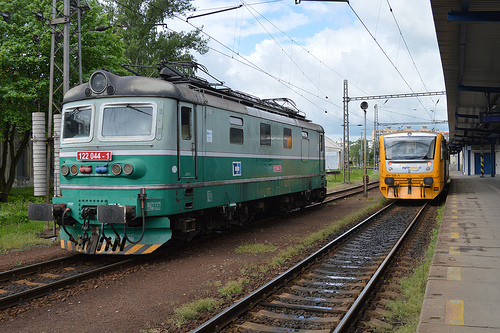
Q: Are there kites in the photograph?
A: No, there are no kites.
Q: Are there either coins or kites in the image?
A: No, there are no kites or coins.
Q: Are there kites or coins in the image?
A: No, there are no kites or coins.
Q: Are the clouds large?
A: Yes, the clouds are large.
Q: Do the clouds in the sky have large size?
A: Yes, the clouds are large.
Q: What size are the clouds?
A: The clouds are large.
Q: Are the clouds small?
A: No, the clouds are large.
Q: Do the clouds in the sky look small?
A: No, the clouds are large.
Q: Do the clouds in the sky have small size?
A: No, the clouds are large.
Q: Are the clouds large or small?
A: The clouds are large.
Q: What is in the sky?
A: The clouds are in the sky.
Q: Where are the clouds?
A: The clouds are in the sky.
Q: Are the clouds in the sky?
A: Yes, the clouds are in the sky.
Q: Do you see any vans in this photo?
A: No, there are no vans.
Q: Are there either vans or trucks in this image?
A: No, there are no vans or trucks.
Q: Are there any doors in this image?
A: Yes, there is a door.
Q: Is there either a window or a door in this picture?
A: Yes, there is a door.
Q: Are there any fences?
A: No, there are no fences.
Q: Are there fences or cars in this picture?
A: No, there are no fences or cars.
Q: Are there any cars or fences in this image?
A: No, there are no fences or cars.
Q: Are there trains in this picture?
A: Yes, there is a train.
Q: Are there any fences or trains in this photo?
A: Yes, there is a train.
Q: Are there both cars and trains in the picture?
A: No, there is a train but no cars.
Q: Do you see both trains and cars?
A: No, there is a train but no cars.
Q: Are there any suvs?
A: No, there are no suvs.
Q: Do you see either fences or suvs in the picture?
A: No, there are no suvs or fences.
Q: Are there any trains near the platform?
A: Yes, there is a train near the platform.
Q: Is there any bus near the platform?
A: No, there is a train near the platform.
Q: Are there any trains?
A: Yes, there is a train.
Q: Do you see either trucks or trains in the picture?
A: Yes, there is a train.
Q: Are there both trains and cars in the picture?
A: No, there is a train but no cars.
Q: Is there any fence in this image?
A: No, there are no fences.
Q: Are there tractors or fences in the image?
A: No, there are no fences or tractors.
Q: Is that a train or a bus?
A: That is a train.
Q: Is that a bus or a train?
A: That is a train.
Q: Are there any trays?
A: No, there are no trays.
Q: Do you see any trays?
A: No, there are no trays.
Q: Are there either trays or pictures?
A: No, there are no trays or pictures.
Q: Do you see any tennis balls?
A: No, there are no tennis balls.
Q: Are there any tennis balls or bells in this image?
A: No, there are no tennis balls or bells.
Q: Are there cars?
A: No, there are no cars.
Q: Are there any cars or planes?
A: No, there are no cars or planes.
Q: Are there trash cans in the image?
A: No, there are no trash cans.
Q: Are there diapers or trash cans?
A: No, there are no trash cans or diapers.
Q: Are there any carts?
A: No, there are no carts.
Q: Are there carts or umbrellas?
A: No, there are no carts or umbrellas.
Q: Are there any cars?
A: No, there are no cars.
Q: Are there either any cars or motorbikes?
A: No, there are no cars or motorbikes.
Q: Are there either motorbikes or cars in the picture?
A: No, there are no cars or motorbikes.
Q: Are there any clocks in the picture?
A: No, there are no clocks.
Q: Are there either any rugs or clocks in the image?
A: No, there are no clocks or rugs.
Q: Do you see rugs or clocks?
A: No, there are no clocks or rugs.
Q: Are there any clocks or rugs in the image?
A: No, there are no clocks or rugs.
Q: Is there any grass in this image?
A: Yes, there is grass.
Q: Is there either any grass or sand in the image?
A: Yes, there is grass.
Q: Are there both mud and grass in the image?
A: No, there is grass but no mud.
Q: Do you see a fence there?
A: No, there are no fences.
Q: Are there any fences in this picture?
A: No, there are no fences.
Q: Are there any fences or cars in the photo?
A: No, there are no fences or cars.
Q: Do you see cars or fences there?
A: No, there are no fences or cars.